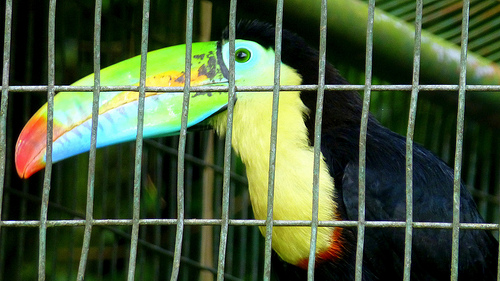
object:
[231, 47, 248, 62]
bird eye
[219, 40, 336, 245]
neck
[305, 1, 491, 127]
pipe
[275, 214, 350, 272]
red feathers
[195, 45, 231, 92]
chipped area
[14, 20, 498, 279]
bird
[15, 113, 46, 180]
orange beak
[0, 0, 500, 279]
cage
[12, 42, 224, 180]
beak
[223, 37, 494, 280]
body